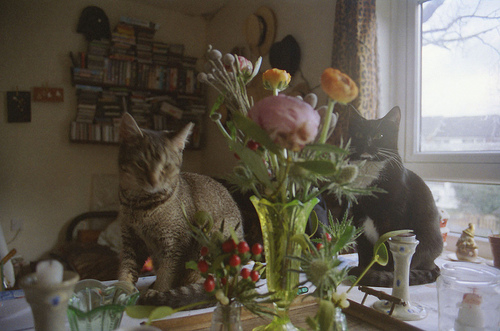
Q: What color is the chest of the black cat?
A: White.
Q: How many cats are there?
A: 2.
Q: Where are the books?
A: On a shelf on the wall.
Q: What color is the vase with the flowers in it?
A: Green.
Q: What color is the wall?
A: White.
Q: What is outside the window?
A: A tree.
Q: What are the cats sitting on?
A: A table.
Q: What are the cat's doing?
A: Sitting on the table.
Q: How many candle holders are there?
A: 2.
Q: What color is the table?
A: White.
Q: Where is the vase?
A: On the table.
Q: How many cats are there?
A: 2.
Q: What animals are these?
A: Cats.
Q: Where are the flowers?
A: In the vase.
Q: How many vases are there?
A: 3.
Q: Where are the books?
A: On the shelf.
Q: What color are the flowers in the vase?
A: Pink and orange.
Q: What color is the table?
A: Brown.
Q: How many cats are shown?
A: 2.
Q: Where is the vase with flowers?
A: Between the cats.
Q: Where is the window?
A: On the right.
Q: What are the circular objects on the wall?
A: Hats.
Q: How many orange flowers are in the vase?
A: 2.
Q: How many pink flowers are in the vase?
A: 1.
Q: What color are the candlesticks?
A: White.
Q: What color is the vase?
A: Green.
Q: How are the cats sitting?
A: Upright.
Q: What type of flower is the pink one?
A: Peony.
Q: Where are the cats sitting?
A: On the table.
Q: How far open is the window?
A: 1/4.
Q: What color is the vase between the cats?
A: Green.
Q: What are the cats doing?
A: Sitting.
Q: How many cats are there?
A: Two.